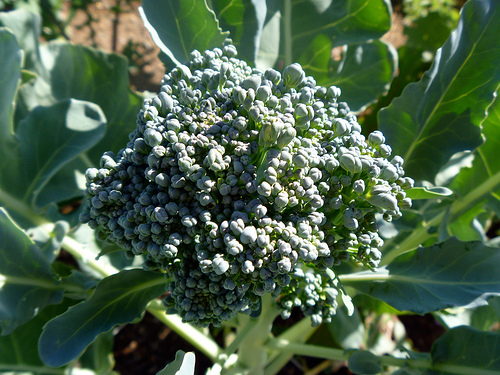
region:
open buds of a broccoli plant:
[81, 46, 414, 331]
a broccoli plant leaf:
[38, 269, 175, 366]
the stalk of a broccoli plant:
[235, 297, 285, 372]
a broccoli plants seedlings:
[280, 60, 300, 85]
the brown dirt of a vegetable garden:
[60, 0, 160, 85]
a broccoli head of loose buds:
[76, 41, 408, 321]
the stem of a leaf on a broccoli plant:
[280, 338, 345, 363]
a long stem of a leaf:
[28, 213, 232, 369]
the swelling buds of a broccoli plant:
[341, 151, 363, 176]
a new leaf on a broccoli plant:
[407, 186, 453, 200]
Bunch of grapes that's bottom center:
[267, 267, 344, 329]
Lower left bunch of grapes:
[153, 206, 275, 278]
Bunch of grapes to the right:
[59, 129, 236, 206]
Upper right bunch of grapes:
[134, 81, 199, 133]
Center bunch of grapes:
[256, 145, 336, 217]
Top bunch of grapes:
[181, 45, 263, 100]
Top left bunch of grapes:
[282, 65, 353, 131]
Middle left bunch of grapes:
[328, 131, 418, 220]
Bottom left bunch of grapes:
[331, 227, 372, 278]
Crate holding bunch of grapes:
[51, 211, 394, 373]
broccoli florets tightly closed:
[42, 15, 448, 346]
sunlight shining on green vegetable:
[81, 30, 456, 335]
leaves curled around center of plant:
[40, 37, 455, 352]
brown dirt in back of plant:
[45, 12, 455, 77]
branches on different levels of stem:
[57, 240, 403, 361]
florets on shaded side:
[106, 167, 221, 337]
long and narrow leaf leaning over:
[25, 245, 180, 366]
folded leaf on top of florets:
[115, 0, 260, 92]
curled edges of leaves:
[365, 5, 405, 100]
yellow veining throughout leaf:
[397, 18, 488, 169]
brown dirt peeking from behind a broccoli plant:
[52, 5, 188, 94]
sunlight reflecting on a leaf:
[374, 258, 476, 305]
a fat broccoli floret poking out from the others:
[280, 62, 305, 91]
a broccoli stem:
[232, 293, 281, 373]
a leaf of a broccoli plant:
[0, 91, 110, 205]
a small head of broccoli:
[88, 44, 429, 314]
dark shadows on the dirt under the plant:
[107, 318, 205, 370]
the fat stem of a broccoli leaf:
[73, 239, 218, 348]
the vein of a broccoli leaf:
[84, 273, 163, 322]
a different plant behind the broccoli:
[73, 7, 125, 50]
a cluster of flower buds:
[106, 61, 424, 342]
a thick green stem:
[219, 301, 290, 373]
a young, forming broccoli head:
[76, 45, 422, 330]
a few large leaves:
[5, 51, 130, 196]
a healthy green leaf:
[27, 262, 173, 369]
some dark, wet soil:
[113, 317, 182, 373]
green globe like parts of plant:
[198, 197, 322, 283]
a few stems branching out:
[191, 302, 318, 369]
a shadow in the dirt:
[114, 45, 194, 110]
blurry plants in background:
[375, 0, 462, 83]